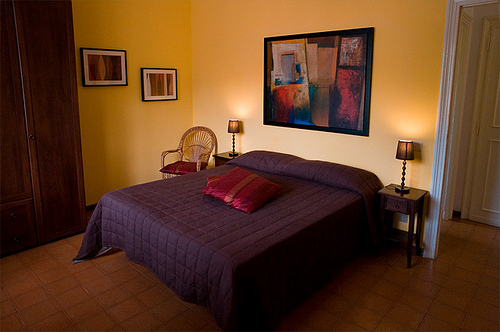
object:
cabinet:
[0, 0, 87, 255]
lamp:
[228, 120, 240, 156]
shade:
[236, 121, 245, 155]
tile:
[343, 292, 390, 331]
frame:
[262, 27, 374, 138]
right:
[377, 182, 428, 268]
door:
[458, 3, 498, 227]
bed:
[70, 150, 383, 331]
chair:
[158, 125, 218, 180]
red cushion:
[159, 161, 208, 175]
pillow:
[202, 166, 283, 214]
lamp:
[394, 138, 414, 193]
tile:
[43, 276, 91, 311]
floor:
[0, 220, 500, 331]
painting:
[83, 49, 127, 85]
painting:
[142, 69, 177, 101]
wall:
[73, 0, 190, 203]